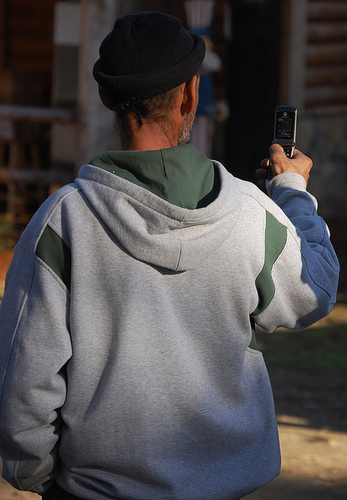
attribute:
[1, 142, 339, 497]
sweater — green, gray, hooded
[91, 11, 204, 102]
hat — black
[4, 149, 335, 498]
shirt — grey, hooded, sweat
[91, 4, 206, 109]
hat — black 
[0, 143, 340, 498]
sweat shirt — grey 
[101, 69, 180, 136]
hair — brown